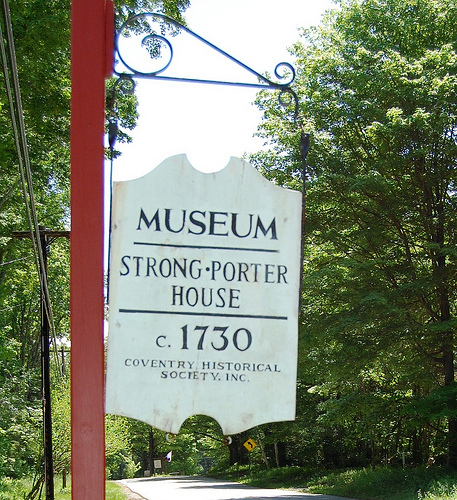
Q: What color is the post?
A: Red.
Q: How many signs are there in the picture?
A: One.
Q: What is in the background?
A: Trees.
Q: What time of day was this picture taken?
A: Daytime.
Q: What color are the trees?
A: Green.